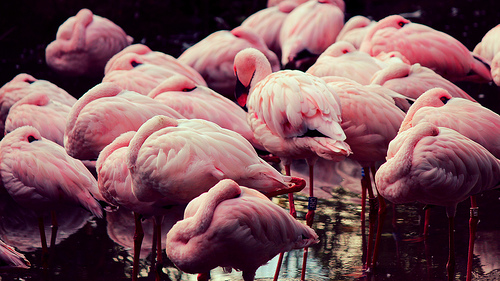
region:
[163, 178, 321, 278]
a resting pink flamingo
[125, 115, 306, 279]
a resting pink flamingo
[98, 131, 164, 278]
a resting pink flamingo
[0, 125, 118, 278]
a resting pink flamingo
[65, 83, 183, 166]
a resting pink flamingo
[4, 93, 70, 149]
a resting pink flamingo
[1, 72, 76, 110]
a resting pink flamingo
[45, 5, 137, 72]
a resting pink flamingo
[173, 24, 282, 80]
a resting pink flamingo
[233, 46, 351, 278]
a resting pink flamingo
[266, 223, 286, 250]
part of a wing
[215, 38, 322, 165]
the flamingo is pink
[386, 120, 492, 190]
the flamingo is pink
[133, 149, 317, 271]
the flamingo is pink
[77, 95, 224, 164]
the flamingo is pink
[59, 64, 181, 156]
the flamingo is pink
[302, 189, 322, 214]
tag attached to bird's leg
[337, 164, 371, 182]
tag attached to bird's leg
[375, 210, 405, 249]
tag attached to bird's leg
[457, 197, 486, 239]
tag attached to bird's leg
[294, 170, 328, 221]
tag attached to bird's leg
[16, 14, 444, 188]
A flock of pink flamingoes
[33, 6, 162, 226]
The flamingoes are all sleeping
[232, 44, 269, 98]
This bird doesnt have its head tucked away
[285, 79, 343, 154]
The tail feathers of a pink flamingo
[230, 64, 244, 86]
The flamingo has black around its eyes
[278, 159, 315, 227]
The legs are orange in color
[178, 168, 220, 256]
The long pink neck of a flamingo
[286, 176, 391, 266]
The birds are standing in water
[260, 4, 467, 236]
The birds are standing and sleeping in water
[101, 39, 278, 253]
The birds are asleep standing up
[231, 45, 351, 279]
A flamingo without its head tucked in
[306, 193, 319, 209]
A blue tag on the leg of the flamingo with an untucked head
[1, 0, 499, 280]
A herd of flamingos sleeping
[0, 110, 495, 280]
Shallow, calm water with flamingo reflection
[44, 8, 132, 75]
A flamingo sleeping a bit away from the herd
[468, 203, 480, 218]
A tag on the leg of the flamingo to the right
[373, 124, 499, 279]
A tagged flamingo to the right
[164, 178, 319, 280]
A sleeping flamingo in front of the others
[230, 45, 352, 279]
A flamingo standing on both legs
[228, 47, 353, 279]
An awake flamingo in the middle of the herd